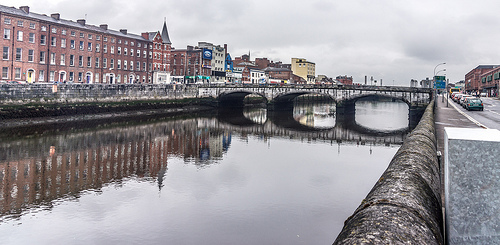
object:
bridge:
[211, 84, 428, 108]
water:
[0, 101, 412, 245]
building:
[0, 5, 211, 83]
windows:
[77, 41, 86, 51]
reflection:
[22, 132, 244, 185]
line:
[447, 99, 488, 128]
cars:
[468, 99, 484, 110]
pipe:
[346, 100, 442, 218]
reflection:
[184, 115, 235, 171]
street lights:
[433, 63, 445, 93]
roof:
[152, 17, 180, 40]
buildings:
[463, 64, 499, 99]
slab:
[443, 126, 499, 245]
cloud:
[351, 23, 420, 44]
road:
[450, 94, 500, 129]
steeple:
[158, 19, 172, 31]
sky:
[0, 0, 500, 86]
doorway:
[28, 68, 35, 83]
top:
[164, 16, 166, 24]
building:
[291, 57, 316, 86]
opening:
[219, 90, 267, 104]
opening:
[267, 91, 341, 109]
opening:
[344, 94, 413, 119]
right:
[452, 76, 459, 78]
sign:
[203, 48, 211, 59]